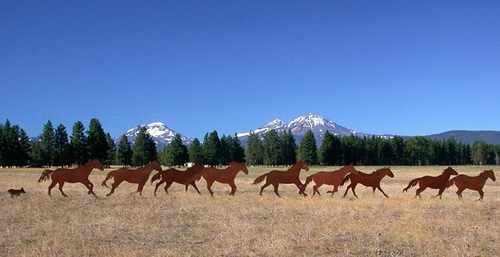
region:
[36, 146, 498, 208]
horses running in a field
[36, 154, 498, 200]
horses are brown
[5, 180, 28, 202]
a dog running behind horses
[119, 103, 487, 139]
mountains behind the trees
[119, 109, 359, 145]
top of mountains are covered with snow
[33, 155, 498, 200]
horses running to the right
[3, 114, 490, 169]
green trees on side of a field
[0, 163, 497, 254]
field is covered with dry grass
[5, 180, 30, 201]
dog is color brown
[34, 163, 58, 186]
tail of a horse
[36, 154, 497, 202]
nine horse running to the right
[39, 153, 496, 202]
horses are in motion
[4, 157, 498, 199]
a dog running behind horses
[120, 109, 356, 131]
mountain peaks are covered with snow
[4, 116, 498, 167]
trees on side a field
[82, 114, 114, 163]
a green big tree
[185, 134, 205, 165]
a small green tree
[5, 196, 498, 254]
a field covered with dry grass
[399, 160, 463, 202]
a horse color dark brown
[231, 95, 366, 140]
a snow covered mountain.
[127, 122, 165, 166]
a tall pine tree.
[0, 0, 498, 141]
a crystal blue sky.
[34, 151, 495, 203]
a herd of wild horses.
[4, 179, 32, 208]
a dog chasing a horse.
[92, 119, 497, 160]
a snow covered mountain range.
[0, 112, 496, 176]
a lush green forest.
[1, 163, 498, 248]
a field of dry grass.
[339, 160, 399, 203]
a horse running near other horses.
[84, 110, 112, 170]
a large pine tree.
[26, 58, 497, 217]
horses running in a field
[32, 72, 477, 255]
brown horses running in a field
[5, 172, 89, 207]
a dog running in a field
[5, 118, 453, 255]
a dog running after horses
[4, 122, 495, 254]
a dog running after brown horses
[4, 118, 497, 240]
a dog running in tall grass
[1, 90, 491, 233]
horses and dog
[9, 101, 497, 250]
brown horses and a dog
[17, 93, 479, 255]
a field of green grass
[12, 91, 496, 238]
horses in a grass field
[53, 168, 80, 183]
a brown horse running wild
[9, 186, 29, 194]
a black dog chasing the horses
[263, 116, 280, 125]
the white mountain top in the background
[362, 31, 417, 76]
the clear blue sky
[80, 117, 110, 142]
the green pine tree in the background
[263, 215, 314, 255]
the brown grass in the foreground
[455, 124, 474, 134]
the mountains in the distance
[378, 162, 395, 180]
one of the horses head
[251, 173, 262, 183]
the brown tail of one of the horses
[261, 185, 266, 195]
the leg of one of the horses